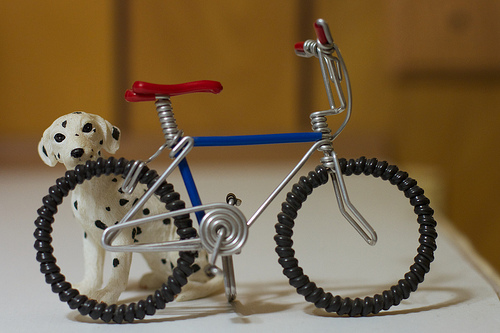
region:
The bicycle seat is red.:
[121, 73, 224, 99]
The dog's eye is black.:
[80, 121, 98, 136]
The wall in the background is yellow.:
[247, 66, 280, 104]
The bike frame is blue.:
[213, 131, 300, 143]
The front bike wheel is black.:
[276, 163, 441, 323]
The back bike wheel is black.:
[33, 160, 190, 322]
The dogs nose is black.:
[70, 145, 86, 159]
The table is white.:
[325, 231, 353, 273]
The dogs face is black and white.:
[38, 110, 123, 161]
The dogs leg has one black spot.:
[103, 251, 130, 294]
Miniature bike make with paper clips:
[32, 12, 440, 319]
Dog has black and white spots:
[33, 108, 200, 282]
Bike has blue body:
[171, 131, 337, 213]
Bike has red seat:
[122, 80, 227, 100]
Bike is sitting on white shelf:
[310, 211, 348, 268]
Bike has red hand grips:
[291, 38, 310, 55]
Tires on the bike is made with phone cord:
[271, 158, 443, 315]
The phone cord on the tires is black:
[271, 163, 438, 319]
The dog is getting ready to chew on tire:
[30, 113, 125, 194]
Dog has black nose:
[35, 111, 124, 163]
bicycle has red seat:
[128, 80, 226, 110]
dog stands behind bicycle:
[33, 113, 242, 298]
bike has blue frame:
[168, 132, 372, 261]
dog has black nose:
[68, 140, 84, 162]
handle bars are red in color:
[287, 14, 351, 67]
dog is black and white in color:
[33, 106, 233, 318]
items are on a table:
[31, 18, 443, 320]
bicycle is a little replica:
[35, 15, 438, 319]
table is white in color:
[48, 176, 494, 327]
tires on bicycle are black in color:
[35, 159, 432, 327]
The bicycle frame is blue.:
[207, 129, 298, 151]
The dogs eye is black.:
[52, 128, 64, 143]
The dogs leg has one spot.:
[108, 254, 130, 289]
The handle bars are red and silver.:
[281, 19, 333, 54]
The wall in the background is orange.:
[226, 20, 281, 69]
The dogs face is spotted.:
[33, 110, 116, 160]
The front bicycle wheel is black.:
[276, 162, 438, 309]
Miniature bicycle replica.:
[24, 16, 429, 319]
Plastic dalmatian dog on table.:
[34, 106, 223, 300]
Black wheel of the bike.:
[272, 158, 440, 313]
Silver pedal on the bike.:
[201, 260, 224, 279]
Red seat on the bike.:
[127, 73, 230, 105]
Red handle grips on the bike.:
[289, 17, 334, 57]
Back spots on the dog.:
[38, 109, 193, 301]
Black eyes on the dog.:
[40, 109, 100, 172]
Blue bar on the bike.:
[173, 125, 325, 151]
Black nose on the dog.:
[32, 109, 124, 174]